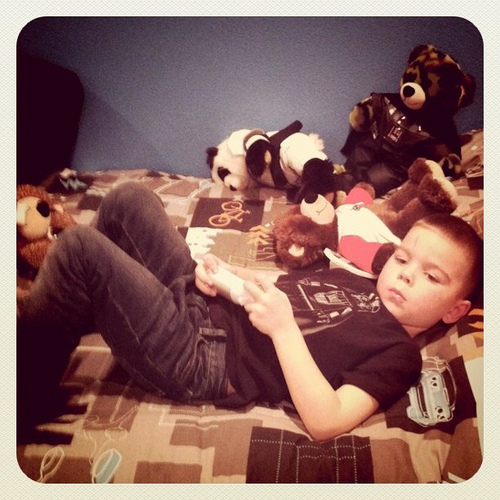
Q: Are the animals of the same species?
A: Yes, all the animals are bears.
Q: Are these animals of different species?
A: No, all the animals are bears.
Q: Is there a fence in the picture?
A: No, there are no fences.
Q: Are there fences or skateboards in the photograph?
A: No, there are no fences or skateboards.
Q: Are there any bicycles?
A: Yes, there is a bicycle.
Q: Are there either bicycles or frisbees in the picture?
A: Yes, there is a bicycle.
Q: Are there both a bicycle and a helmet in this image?
A: No, there is a bicycle but no helmets.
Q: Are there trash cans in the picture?
A: No, there are no trash cans.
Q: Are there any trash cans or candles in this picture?
A: No, there are no trash cans or candles.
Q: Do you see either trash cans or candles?
A: No, there are no trash cans or candles.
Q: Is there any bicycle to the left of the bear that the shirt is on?
A: Yes, there is a bicycle to the left of the bear.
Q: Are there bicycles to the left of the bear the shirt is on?
A: Yes, there is a bicycle to the left of the bear.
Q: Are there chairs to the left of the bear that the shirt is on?
A: No, there is a bicycle to the left of the bear.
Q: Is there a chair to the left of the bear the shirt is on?
A: No, there is a bicycle to the left of the bear.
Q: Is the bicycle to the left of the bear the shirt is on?
A: Yes, the bicycle is to the left of the bear.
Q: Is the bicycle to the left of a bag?
A: No, the bicycle is to the left of the bear.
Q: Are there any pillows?
A: No, there are no pillows.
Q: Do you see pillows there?
A: No, there are no pillows.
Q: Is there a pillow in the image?
A: No, there are no pillows.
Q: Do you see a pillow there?
A: No, there are no pillows.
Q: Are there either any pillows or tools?
A: No, there are no pillows or tools.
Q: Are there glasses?
A: No, there are no glasses.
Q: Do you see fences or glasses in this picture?
A: No, there are no glasses or fences.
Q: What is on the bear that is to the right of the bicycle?
A: The shirt is on the bear.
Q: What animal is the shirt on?
A: The shirt is on the bear.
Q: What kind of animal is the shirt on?
A: The shirt is on the bear.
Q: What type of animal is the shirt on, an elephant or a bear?
A: The shirt is on a bear.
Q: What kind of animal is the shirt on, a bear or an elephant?
A: The shirt is on a bear.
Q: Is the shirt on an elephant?
A: No, the shirt is on the bear.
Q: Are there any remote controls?
A: Yes, there is a remote control.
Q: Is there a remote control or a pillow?
A: Yes, there is a remote control.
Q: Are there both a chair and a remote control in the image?
A: No, there is a remote control but no chairs.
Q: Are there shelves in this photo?
A: No, there are no shelves.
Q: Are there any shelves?
A: No, there are no shelves.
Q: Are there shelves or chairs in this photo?
A: No, there are no shelves or chairs.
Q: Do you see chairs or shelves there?
A: No, there are no shelves or chairs.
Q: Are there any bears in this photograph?
A: Yes, there is a bear.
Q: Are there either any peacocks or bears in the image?
A: Yes, there is a bear.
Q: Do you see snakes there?
A: No, there are no snakes.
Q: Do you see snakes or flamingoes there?
A: No, there are no snakes or flamingoes.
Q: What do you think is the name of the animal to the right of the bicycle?
A: The animal is a bear.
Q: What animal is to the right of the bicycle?
A: The animal is a bear.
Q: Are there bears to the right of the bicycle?
A: Yes, there is a bear to the right of the bicycle.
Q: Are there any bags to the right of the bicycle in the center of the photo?
A: No, there is a bear to the right of the bicycle.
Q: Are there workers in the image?
A: No, there are no workers.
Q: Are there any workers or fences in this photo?
A: No, there are no workers or fences.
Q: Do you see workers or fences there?
A: No, there are no workers or fences.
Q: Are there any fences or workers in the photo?
A: No, there are no workers or fences.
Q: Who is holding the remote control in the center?
A: The boy is holding the remote control.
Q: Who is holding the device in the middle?
A: The boy is holding the remote control.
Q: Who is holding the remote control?
A: The boy is holding the remote control.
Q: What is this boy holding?
A: The boy is holding the remote control.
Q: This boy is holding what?
A: The boy is holding the remote control.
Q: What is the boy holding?
A: The boy is holding the remote control.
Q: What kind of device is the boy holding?
A: The boy is holding the remote.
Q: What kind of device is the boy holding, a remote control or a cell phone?
A: The boy is holding a remote control.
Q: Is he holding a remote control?
A: Yes, the boy is holding a remote control.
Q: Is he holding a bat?
A: No, the boy is holding a remote control.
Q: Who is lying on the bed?
A: The boy is lying on the bed.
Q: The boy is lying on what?
A: The boy is lying on the bed.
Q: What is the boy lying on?
A: The boy is lying on the bed.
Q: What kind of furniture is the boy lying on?
A: The boy is lying on the bed.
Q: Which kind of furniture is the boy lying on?
A: The boy is lying on the bed.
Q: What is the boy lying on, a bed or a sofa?
A: The boy is lying on a bed.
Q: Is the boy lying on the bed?
A: Yes, the boy is lying on the bed.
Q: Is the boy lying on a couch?
A: No, the boy is lying on the bed.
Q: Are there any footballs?
A: Yes, there is a football.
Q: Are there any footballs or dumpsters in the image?
A: Yes, there is a football.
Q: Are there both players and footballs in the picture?
A: No, there is a football but no players.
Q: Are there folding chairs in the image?
A: No, there are no folding chairs.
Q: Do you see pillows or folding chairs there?
A: No, there are no folding chairs or pillows.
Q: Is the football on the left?
A: Yes, the football is on the left of the image.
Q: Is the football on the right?
A: No, the football is on the left of the image.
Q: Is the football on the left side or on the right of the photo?
A: The football is on the left of the image.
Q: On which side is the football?
A: The football is on the left of the image.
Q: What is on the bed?
A: The football is on the bed.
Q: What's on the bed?
A: The football is on the bed.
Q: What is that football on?
A: The football is on the bed.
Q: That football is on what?
A: The football is on the bed.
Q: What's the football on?
A: The football is on the bed.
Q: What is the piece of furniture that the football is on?
A: The piece of furniture is a bed.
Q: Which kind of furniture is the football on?
A: The football is on the bed.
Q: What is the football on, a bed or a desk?
A: The football is on a bed.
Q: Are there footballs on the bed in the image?
A: Yes, there is a football on the bed.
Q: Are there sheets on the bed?
A: No, there is a football on the bed.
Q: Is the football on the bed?
A: Yes, the football is on the bed.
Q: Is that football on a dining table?
A: No, the football is on the bed.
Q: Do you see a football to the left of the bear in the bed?
A: Yes, there is a football to the left of the bear.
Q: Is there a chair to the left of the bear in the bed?
A: No, there is a football to the left of the bear.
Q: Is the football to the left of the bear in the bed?
A: Yes, the football is to the left of the bear.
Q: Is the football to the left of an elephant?
A: No, the football is to the left of the bear.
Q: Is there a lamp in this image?
A: No, there are no lamps.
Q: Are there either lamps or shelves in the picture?
A: No, there are no lamps or shelves.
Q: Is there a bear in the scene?
A: Yes, there is a bear.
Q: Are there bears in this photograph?
A: Yes, there is a bear.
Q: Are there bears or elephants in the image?
A: Yes, there is a bear.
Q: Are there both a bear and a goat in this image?
A: No, there is a bear but no goats.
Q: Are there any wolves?
A: No, there are no wolves.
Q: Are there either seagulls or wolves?
A: No, there are no wolves or seagulls.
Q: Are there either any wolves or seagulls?
A: No, there are no wolves or seagulls.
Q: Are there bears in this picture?
A: Yes, there is a bear.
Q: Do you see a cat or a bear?
A: Yes, there is a bear.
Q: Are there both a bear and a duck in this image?
A: No, there is a bear but no ducks.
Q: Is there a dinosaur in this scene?
A: No, there are no dinosaurs.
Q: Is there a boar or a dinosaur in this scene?
A: No, there are no dinosaurs or boars.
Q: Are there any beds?
A: Yes, there is a bed.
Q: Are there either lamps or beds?
A: Yes, there is a bed.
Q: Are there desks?
A: No, there are no desks.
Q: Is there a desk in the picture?
A: No, there are no desks.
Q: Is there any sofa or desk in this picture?
A: No, there are no desks or sofas.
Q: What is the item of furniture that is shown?
A: The piece of furniture is a bed.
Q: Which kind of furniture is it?
A: The piece of furniture is a bed.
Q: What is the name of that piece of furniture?
A: This is a bed.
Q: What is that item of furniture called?
A: This is a bed.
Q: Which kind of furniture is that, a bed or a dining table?
A: This is a bed.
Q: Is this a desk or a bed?
A: This is a bed.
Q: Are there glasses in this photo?
A: No, there are no glasses.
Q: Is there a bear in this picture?
A: Yes, there is a bear.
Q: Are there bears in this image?
A: Yes, there is a bear.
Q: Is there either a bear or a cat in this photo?
A: Yes, there is a bear.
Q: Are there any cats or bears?
A: Yes, there is a bear.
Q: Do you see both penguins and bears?
A: No, there is a bear but no penguins.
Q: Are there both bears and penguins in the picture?
A: No, there is a bear but no penguins.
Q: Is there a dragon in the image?
A: No, there are no dragons.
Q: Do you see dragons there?
A: No, there are no dragons.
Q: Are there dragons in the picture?
A: No, there are no dragons.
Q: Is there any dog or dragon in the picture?
A: No, there are no dragons or dogs.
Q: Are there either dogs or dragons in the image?
A: No, there are no dragons or dogs.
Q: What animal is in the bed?
A: The bear is in the bed.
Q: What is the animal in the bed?
A: The animal is a bear.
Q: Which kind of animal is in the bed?
A: The animal is a bear.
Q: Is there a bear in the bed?
A: Yes, there is a bear in the bed.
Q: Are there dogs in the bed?
A: No, there is a bear in the bed.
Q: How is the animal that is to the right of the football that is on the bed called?
A: The animal is a bear.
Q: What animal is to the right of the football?
A: The animal is a bear.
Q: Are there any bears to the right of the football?
A: Yes, there is a bear to the right of the football.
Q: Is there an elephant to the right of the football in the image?
A: No, there is a bear to the right of the football.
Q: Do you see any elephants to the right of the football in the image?
A: No, there is a bear to the right of the football.